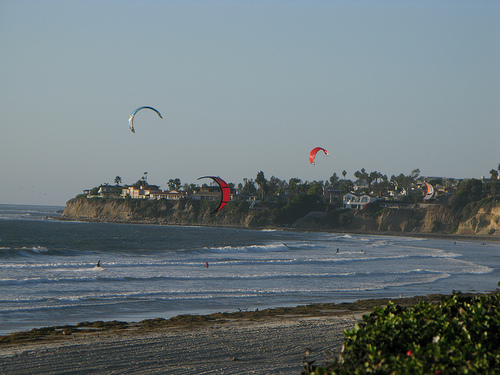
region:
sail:
[195, 161, 238, 220]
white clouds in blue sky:
[17, 29, 57, 59]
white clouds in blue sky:
[388, 35, 429, 73]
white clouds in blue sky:
[430, 61, 450, 79]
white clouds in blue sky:
[357, 41, 392, 69]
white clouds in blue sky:
[231, 1, 279, 45]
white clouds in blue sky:
[215, 52, 267, 104]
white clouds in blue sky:
[187, 45, 215, 73]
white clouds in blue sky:
[85, 9, 143, 69]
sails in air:
[124, 93, 156, 140]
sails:
[190, 155, 252, 226]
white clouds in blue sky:
[383, 8, 433, 43]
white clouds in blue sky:
[406, 100, 437, 126]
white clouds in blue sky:
[254, 29, 298, 67]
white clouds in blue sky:
[227, 125, 295, 185]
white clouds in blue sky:
[31, 126, 58, 150]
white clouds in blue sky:
[75, 32, 122, 107]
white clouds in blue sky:
[191, 19, 245, 49]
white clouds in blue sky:
[298, 51, 329, 73]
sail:
[287, 124, 340, 190]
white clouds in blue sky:
[398, 13, 449, 45]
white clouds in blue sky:
[404, 102, 458, 137]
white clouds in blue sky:
[332, 42, 372, 74]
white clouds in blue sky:
[252, 66, 284, 114]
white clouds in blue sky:
[201, 5, 223, 37]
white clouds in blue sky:
[58, 62, 83, 77]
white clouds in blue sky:
[37, 108, 69, 139]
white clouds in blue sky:
[52, 23, 86, 58]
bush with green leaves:
[334, 294, 498, 374]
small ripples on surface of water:
[69, 222, 175, 249]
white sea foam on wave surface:
[248, 242, 288, 252]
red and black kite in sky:
[187, 159, 244, 223]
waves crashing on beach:
[430, 244, 497, 291]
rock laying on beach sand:
[222, 352, 249, 367]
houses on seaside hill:
[78, 174, 208, 212]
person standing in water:
[82, 249, 120, 281]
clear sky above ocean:
[0, 0, 432, 107]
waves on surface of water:
[240, 244, 326, 304]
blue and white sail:
[117, 92, 172, 144]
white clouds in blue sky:
[427, 71, 464, 128]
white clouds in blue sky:
[372, 71, 414, 115]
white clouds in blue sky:
[261, 39, 279, 56]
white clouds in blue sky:
[22, 63, 96, 111]